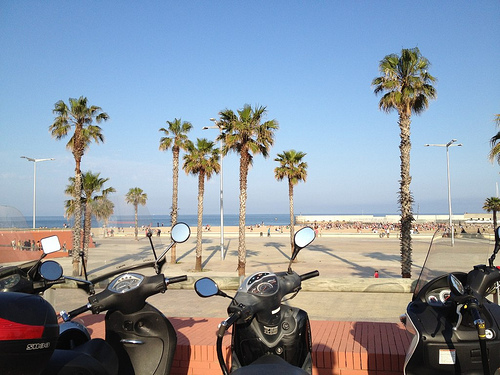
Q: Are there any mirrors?
A: Yes, there is a mirror.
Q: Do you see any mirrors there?
A: Yes, there is a mirror.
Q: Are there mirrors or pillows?
A: Yes, there is a mirror.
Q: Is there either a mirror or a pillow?
A: Yes, there is a mirror.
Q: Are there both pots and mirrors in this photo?
A: No, there is a mirror but no pots.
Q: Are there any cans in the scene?
A: No, there are no cans.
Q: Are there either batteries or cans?
A: No, there are no cans or batteries.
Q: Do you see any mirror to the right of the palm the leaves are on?
A: Yes, there is a mirror to the right of the palm.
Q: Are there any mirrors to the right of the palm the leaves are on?
A: Yes, there is a mirror to the right of the palm.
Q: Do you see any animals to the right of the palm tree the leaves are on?
A: No, there is a mirror to the right of the palm.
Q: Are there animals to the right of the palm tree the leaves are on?
A: No, there is a mirror to the right of the palm.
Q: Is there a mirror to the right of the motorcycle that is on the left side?
A: Yes, there is a mirror to the right of the motorcycle.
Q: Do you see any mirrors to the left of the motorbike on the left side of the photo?
A: No, the mirror is to the right of the motorcycle.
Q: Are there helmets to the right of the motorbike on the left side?
A: No, there is a mirror to the right of the motorbike.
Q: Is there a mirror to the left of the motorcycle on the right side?
A: Yes, there is a mirror to the left of the motorbike.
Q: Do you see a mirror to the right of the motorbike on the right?
A: No, the mirror is to the left of the motorcycle.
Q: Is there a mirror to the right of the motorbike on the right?
A: No, the mirror is to the left of the motorcycle.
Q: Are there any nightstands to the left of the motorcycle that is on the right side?
A: No, there is a mirror to the left of the motorcycle.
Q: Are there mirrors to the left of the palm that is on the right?
A: Yes, there is a mirror to the left of the palm tree.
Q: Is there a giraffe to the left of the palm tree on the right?
A: No, there is a mirror to the left of the palm.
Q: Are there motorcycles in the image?
A: Yes, there is a motorcycle.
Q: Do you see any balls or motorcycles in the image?
A: Yes, there is a motorcycle.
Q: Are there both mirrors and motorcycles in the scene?
A: Yes, there are both a motorcycle and a mirror.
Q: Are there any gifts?
A: No, there are no gifts.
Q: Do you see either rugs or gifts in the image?
A: No, there are no gifts or rugs.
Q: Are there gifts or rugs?
A: No, there are no gifts or rugs.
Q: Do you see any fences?
A: No, there are no fences.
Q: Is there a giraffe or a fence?
A: No, there are no fences or giraffes.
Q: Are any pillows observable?
A: No, there are no pillows.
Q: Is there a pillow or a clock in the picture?
A: No, there are no pillows or clocks.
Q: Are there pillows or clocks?
A: No, there are no pillows or clocks.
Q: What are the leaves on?
A: The leaves are on the palm.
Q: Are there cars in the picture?
A: No, there are no cars.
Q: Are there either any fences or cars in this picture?
A: No, there are no cars or fences.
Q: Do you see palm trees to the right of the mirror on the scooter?
A: Yes, there is a palm tree to the right of the mirror.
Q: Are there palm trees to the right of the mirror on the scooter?
A: Yes, there is a palm tree to the right of the mirror.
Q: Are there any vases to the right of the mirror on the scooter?
A: No, there is a palm tree to the right of the mirror.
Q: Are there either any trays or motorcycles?
A: Yes, there is a motorcycle.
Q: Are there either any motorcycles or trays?
A: Yes, there is a motorcycle.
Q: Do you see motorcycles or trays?
A: Yes, there is a motorcycle.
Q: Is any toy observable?
A: No, there are no toys.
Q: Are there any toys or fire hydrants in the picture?
A: No, there are no toys or fire hydrants.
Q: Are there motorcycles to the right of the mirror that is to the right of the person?
A: Yes, there is a motorcycle to the right of the mirror.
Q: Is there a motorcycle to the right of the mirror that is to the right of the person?
A: Yes, there is a motorcycle to the right of the mirror.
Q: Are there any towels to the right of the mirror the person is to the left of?
A: No, there is a motorcycle to the right of the mirror.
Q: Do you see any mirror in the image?
A: Yes, there is a mirror.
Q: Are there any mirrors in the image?
A: Yes, there is a mirror.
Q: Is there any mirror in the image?
A: Yes, there is a mirror.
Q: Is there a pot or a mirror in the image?
A: Yes, there is a mirror.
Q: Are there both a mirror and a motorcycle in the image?
A: Yes, there are both a mirror and a motorcycle.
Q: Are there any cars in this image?
A: No, there are no cars.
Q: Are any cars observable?
A: No, there are no cars.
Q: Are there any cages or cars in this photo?
A: No, there are no cars or cages.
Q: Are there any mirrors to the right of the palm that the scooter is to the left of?
A: Yes, there is a mirror to the right of the palm.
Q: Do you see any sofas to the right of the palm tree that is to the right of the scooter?
A: No, there is a mirror to the right of the palm.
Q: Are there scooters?
A: Yes, there is a scooter.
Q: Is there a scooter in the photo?
A: Yes, there is a scooter.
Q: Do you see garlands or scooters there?
A: Yes, there is a scooter.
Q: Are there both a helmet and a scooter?
A: No, there is a scooter but no helmets.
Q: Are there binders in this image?
A: No, there are no binders.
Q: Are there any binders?
A: No, there are no binders.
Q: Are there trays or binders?
A: No, there are no binders or trays.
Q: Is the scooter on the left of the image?
A: Yes, the scooter is on the left of the image.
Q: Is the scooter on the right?
A: No, the scooter is on the left of the image.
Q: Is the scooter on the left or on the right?
A: The scooter is on the left of the image.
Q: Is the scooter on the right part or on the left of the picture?
A: The scooter is on the left of the image.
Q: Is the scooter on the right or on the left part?
A: The scooter is on the left of the image.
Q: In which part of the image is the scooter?
A: The scooter is on the left of the image.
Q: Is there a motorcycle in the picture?
A: Yes, there is a motorcycle.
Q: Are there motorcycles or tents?
A: Yes, there is a motorcycle.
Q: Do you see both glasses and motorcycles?
A: No, there is a motorcycle but no glasses.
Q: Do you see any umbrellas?
A: No, there are no umbrellas.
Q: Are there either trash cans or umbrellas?
A: No, there are no umbrellas or trash cans.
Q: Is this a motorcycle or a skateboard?
A: This is a motorcycle.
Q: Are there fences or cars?
A: No, there are no fences or cars.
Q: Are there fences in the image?
A: No, there are no fences.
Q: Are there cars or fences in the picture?
A: No, there are no fences or cars.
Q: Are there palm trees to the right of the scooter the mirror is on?
A: Yes, there is a palm tree to the right of the scooter.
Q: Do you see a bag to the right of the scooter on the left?
A: No, there is a palm tree to the right of the scooter.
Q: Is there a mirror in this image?
A: Yes, there is a mirror.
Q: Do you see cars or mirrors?
A: Yes, there is a mirror.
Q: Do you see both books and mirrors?
A: No, there is a mirror but no books.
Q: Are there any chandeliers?
A: No, there are no chandeliers.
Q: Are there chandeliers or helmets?
A: No, there are no chandeliers or helmets.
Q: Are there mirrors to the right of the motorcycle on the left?
A: Yes, there is a mirror to the right of the motorbike.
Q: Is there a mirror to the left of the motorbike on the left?
A: No, the mirror is to the right of the motorcycle.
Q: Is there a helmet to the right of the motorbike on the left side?
A: No, there is a mirror to the right of the motorcycle.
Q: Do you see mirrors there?
A: Yes, there is a mirror.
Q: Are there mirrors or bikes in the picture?
A: Yes, there is a mirror.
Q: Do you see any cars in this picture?
A: No, there are no cars.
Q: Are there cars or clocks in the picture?
A: No, there are no cars or clocks.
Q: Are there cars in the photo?
A: No, there are no cars.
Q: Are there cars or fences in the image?
A: No, there are no cars or fences.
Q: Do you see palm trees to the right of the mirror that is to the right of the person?
A: Yes, there is a palm tree to the right of the mirror.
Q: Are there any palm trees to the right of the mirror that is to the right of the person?
A: Yes, there is a palm tree to the right of the mirror.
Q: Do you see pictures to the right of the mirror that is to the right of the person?
A: No, there is a palm tree to the right of the mirror.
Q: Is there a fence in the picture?
A: No, there are no fences.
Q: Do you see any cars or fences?
A: No, there are no fences or cars.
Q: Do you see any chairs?
A: No, there are no chairs.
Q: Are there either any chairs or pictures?
A: No, there are no chairs or pictures.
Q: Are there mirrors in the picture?
A: Yes, there is a mirror.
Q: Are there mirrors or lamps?
A: Yes, there is a mirror.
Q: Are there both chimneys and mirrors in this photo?
A: No, there is a mirror but no chimneys.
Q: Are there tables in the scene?
A: No, there are no tables.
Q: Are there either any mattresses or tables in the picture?
A: No, there are no tables or mattresses.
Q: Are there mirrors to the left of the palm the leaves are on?
A: Yes, there is a mirror to the left of the palm tree.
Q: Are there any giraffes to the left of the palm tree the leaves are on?
A: No, there is a mirror to the left of the palm.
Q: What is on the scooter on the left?
A: The mirror is on the scooter.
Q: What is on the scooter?
A: The mirror is on the scooter.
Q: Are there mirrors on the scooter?
A: Yes, there is a mirror on the scooter.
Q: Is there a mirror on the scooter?
A: Yes, there is a mirror on the scooter.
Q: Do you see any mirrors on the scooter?
A: Yes, there is a mirror on the scooter.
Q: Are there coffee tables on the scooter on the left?
A: No, there is a mirror on the scooter.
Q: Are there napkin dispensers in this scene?
A: No, there are no napkin dispensers.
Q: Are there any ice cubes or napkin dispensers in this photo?
A: No, there are no napkin dispensers or ice cubes.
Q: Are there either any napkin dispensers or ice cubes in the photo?
A: No, there are no napkin dispensers or ice cubes.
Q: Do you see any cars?
A: No, there are no cars.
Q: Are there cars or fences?
A: No, there are no cars or fences.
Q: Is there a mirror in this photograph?
A: Yes, there is a mirror.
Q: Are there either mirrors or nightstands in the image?
A: Yes, there is a mirror.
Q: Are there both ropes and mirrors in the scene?
A: No, there is a mirror but no ropes.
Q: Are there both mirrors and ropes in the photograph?
A: No, there is a mirror but no ropes.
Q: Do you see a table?
A: No, there are no tables.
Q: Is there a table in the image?
A: No, there are no tables.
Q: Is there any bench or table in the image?
A: No, there are no tables or benches.